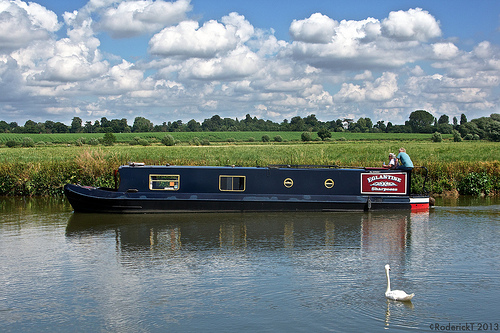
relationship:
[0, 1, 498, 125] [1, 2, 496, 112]
clouds in sky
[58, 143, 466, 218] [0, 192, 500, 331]
boat in calm water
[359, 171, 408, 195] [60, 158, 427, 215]
sign on boat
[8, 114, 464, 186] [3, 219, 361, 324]
fields behind water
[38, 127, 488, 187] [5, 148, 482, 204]
greenery on bank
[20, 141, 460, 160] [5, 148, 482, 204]
weeds on bank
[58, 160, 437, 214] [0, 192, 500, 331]
boat in calm water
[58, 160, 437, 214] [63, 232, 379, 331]
boat in water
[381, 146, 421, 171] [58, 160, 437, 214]
people on boat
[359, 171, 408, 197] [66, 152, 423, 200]
sign on boat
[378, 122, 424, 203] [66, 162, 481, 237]
people standing on boat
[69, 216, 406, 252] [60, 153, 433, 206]
shadow of boat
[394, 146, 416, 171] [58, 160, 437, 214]
people on boat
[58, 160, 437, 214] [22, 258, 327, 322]
boat in water